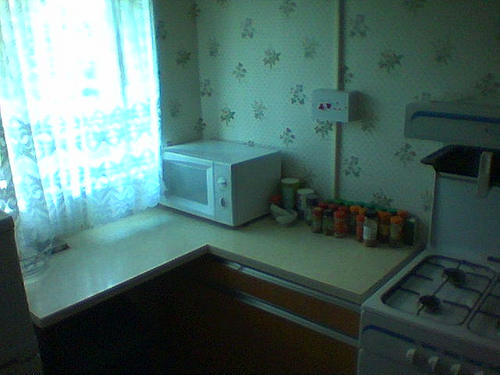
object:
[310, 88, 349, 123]
switch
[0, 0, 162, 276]
white curtain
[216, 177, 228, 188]
knobs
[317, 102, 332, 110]
switches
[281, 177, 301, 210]
spices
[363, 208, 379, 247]
bottles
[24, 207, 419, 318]
countertop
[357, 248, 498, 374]
burner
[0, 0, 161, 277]
window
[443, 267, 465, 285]
gas burner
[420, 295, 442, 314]
gas burner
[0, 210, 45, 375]
fridge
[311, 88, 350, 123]
outlet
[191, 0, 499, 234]
wall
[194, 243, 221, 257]
corner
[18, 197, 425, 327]
counter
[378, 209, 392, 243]
spice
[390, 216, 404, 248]
spice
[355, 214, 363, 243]
spice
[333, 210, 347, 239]
spice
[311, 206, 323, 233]
spice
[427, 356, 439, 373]
knob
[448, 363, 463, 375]
knob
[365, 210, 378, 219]
bottle tops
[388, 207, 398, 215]
bottle tops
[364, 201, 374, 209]
bottle tops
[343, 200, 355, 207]
bottle tops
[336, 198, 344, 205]
bottle tops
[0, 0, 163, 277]
sheers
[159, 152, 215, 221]
microwave door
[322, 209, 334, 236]
spices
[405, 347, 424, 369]
knob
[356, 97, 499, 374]
stove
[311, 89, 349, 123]
box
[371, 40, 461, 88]
wall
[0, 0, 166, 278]
curtain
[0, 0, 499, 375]
kitchen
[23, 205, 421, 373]
cabinet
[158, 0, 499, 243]
wallpaper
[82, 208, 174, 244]
reflection